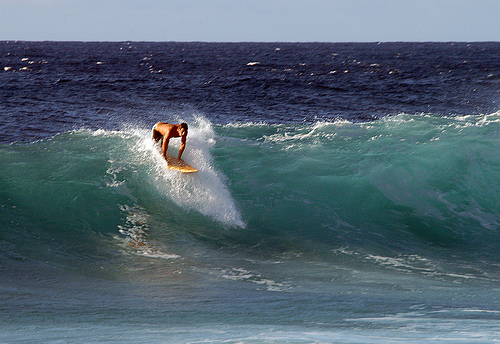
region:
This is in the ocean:
[22, 21, 455, 331]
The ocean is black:
[47, 26, 491, 97]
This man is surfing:
[90, 93, 288, 258]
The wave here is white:
[134, 105, 275, 232]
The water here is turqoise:
[290, 128, 498, 253]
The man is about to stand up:
[92, 103, 264, 263]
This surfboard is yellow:
[159, 145, 214, 182]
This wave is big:
[57, 134, 407, 341]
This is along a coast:
[23, 20, 413, 330]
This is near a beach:
[59, 46, 465, 341]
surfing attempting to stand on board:
[140, 113, 192, 178]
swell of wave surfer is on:
[15, 142, 494, 285]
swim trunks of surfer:
[148, 114, 160, 144]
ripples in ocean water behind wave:
[8, 39, 473, 108]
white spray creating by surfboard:
[99, 139, 174, 253]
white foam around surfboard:
[122, 122, 234, 222]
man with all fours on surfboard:
[149, 114, 201, 179]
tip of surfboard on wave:
[166, 152, 201, 182]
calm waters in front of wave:
[34, 276, 491, 339]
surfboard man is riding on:
[158, 141, 194, 178]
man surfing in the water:
[137, 110, 250, 228]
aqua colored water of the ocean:
[237, 134, 368, 254]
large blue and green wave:
[259, 91, 481, 258]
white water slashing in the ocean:
[103, 124, 153, 194]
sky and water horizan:
[94, 10, 244, 79]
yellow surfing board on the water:
[154, 149, 204, 186]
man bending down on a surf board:
[144, 116, 204, 181]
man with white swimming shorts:
[144, 114, 194, 174]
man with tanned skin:
[154, 112, 199, 179]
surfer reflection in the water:
[117, 219, 217, 296]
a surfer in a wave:
[142, 114, 206, 186]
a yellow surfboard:
[151, 148, 204, 182]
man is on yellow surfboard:
[136, 108, 204, 185]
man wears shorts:
[145, 113, 194, 164]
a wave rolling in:
[22, 101, 492, 237]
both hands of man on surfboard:
[140, 110, 200, 167]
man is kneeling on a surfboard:
[146, 111, 196, 171]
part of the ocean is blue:
[3, 33, 487, 115]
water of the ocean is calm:
[3, 36, 493, 109]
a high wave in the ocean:
[20, 112, 499, 262]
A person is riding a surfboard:
[18, 35, 463, 305]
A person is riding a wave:
[22, 25, 457, 320]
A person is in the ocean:
[12, 40, 467, 326]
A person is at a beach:
[20, 60, 485, 310]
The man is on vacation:
[17, 60, 469, 308]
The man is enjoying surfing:
[15, 20, 470, 325]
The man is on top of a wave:
[20, 21, 487, 301]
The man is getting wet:
[20, 32, 458, 303]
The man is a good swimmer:
[17, 60, 460, 301]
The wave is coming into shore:
[17, 28, 481, 323]